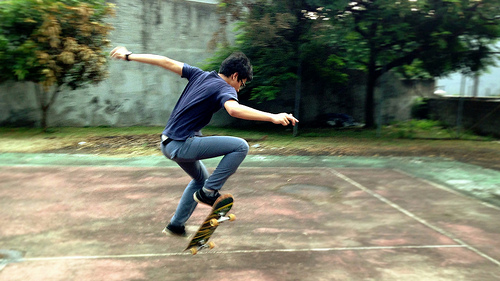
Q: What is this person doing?
A: Skateboarding.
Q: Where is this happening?
A: Basketball court.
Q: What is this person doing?
A: A trick.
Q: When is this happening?
A: During the day.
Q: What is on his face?
A: Glasses.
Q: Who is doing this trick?
A: The boy.